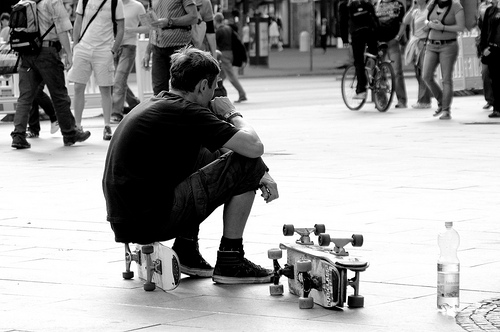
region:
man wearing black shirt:
[137, 125, 162, 155]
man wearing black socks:
[225, 235, 236, 245]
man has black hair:
[182, 61, 195, 83]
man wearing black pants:
[37, 58, 52, 75]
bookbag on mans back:
[10, 5, 37, 48]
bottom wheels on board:
[266, 249, 315, 304]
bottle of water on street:
[430, 209, 467, 314]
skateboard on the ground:
[122, 240, 180, 292]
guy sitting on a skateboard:
[101, 44, 276, 284]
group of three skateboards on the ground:
[268, 223, 370, 310]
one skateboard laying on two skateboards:
[280, 222, 368, 268]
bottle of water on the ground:
[438, 220, 459, 310]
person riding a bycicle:
[341, 0, 395, 112]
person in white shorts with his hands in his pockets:
[69, 0, 124, 140]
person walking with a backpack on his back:
[10, 0, 75, 149]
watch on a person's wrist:
[166, 16, 173, 28]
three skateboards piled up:
[261, 212, 382, 322]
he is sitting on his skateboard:
[85, 175, 271, 313]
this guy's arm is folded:
[145, 37, 290, 202]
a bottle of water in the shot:
[418, 205, 469, 320]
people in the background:
[10, 1, 118, 151]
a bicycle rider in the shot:
[314, 2, 404, 121]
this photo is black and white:
[2, 10, 484, 251]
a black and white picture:
[11, 10, 476, 322]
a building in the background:
[213, 5, 330, 80]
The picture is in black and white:
[6, 2, 492, 324]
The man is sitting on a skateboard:
[95, 35, 292, 288]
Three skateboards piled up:
[258, 203, 377, 328]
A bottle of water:
[422, 213, 465, 319]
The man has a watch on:
[212, 95, 250, 130]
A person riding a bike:
[335, 9, 412, 122]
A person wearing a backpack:
[5, 4, 89, 141]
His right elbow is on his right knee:
[242, 114, 268, 161]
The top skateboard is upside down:
[283, 210, 363, 278]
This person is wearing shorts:
[67, 16, 124, 127]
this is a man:
[86, 0, 300, 298]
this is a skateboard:
[98, 218, 214, 318]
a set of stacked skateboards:
[260, 198, 368, 329]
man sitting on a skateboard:
[66, 41, 279, 309]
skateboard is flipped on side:
[93, 217, 193, 319]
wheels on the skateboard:
[288, 215, 382, 252]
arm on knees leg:
[168, 104, 296, 181]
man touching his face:
[170, 48, 252, 120]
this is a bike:
[336, 16, 418, 128]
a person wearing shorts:
[50, 25, 130, 90]